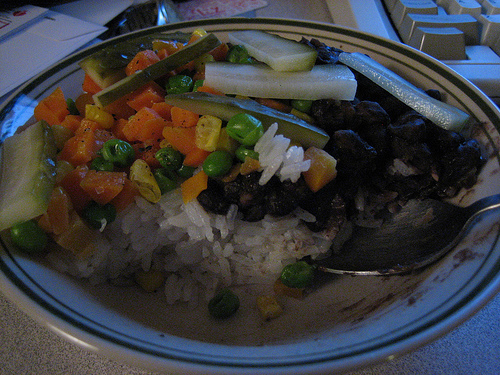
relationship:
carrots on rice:
[38, 53, 228, 217] [123, 201, 334, 316]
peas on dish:
[203, 112, 259, 178] [4, 17, 494, 365]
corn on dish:
[83, 94, 234, 204] [4, 17, 494, 365]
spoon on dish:
[315, 159, 499, 292] [4, 17, 494, 365]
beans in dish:
[186, 32, 474, 142] [4, 17, 494, 365]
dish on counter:
[4, 17, 494, 365] [2, 1, 500, 371]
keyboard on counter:
[331, 1, 498, 103] [2, 1, 500, 371]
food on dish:
[4, 27, 479, 311] [4, 17, 494, 365]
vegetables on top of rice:
[9, 37, 399, 210] [123, 201, 334, 316]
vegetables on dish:
[9, 37, 399, 210] [4, 17, 494, 365]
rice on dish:
[255, 116, 313, 184] [4, 17, 494, 365]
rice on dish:
[123, 201, 334, 316] [4, 17, 494, 365]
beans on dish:
[186, 32, 474, 142] [4, 17, 494, 365]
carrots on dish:
[38, 53, 228, 217] [4, 17, 494, 365]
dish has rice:
[4, 17, 494, 365] [255, 116, 313, 184]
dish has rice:
[4, 17, 494, 365] [123, 201, 334, 316]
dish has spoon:
[4, 17, 494, 365] [315, 159, 499, 292]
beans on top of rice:
[199, 91, 482, 239] [123, 201, 334, 316]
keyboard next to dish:
[331, 1, 498, 103] [4, 17, 494, 365]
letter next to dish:
[2, 3, 105, 119] [4, 17, 494, 365]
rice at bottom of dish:
[123, 201, 334, 316] [4, 17, 494, 365]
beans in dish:
[199, 91, 482, 239] [4, 17, 494, 365]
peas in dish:
[203, 112, 259, 178] [4, 17, 494, 365]